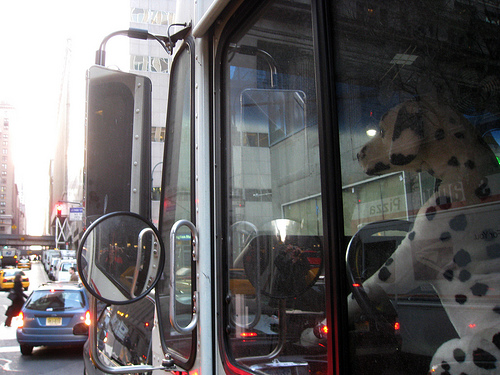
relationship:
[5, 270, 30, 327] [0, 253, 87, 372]
person crossing street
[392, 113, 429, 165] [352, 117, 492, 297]
ear on dog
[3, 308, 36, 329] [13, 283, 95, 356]
light on car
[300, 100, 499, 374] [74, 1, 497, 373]
dog inside bus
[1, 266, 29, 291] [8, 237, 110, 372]
taxi on street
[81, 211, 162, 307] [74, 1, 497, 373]
mirror on bus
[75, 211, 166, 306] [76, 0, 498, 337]
mirror on firetruck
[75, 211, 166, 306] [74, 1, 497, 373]
mirror on bus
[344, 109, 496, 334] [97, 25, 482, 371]
dalmation in fire truck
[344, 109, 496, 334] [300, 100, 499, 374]
dalmation on dog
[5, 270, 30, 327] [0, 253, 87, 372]
person walking across street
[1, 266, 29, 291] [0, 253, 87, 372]
taxi on street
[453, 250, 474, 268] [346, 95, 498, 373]
black spot on dog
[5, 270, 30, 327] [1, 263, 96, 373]
person crossing street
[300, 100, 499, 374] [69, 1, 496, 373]
dog in bus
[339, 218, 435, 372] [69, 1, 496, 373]
steering wheel of bus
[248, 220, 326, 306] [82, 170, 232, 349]
reflection of mirror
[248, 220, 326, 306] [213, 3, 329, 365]
reflection on glass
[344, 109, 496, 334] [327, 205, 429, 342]
dalmation on steering wheel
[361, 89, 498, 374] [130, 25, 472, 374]
dog looks out window